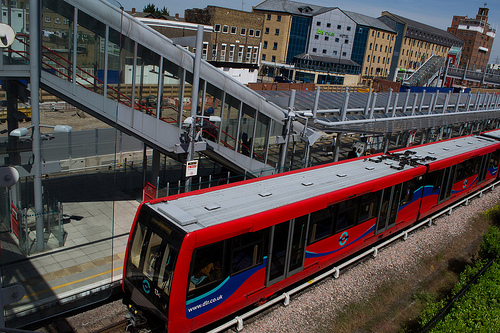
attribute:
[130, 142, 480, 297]
train — red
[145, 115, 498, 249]
roof — gray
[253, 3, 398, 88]
building — brown, tan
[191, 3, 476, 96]
building — brown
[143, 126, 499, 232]
roof — gray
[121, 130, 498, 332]
train — blue, red, gray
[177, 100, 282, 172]
people — walking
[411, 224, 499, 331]
foilage — green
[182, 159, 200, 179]
sign — small, white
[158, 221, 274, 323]
train — red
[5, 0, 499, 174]
structure — gray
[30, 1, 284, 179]
staircase — covered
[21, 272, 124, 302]
line — yellow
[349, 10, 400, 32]
roof — gray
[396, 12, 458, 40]
roof — gray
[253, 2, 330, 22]
roof — gray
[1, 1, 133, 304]
platform — train platform